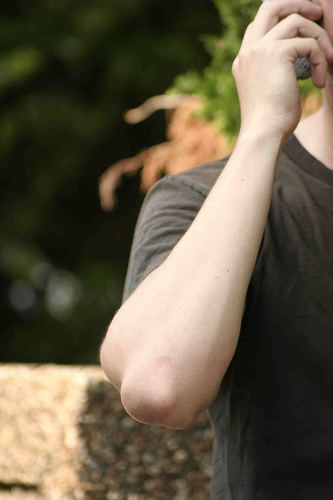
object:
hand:
[230, 0, 332, 136]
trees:
[97, 0, 321, 218]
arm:
[98, 131, 278, 431]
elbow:
[100, 314, 210, 431]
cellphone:
[294, 56, 310, 79]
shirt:
[119, 130, 332, 500]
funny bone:
[119, 357, 178, 426]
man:
[99, 0, 331, 500]